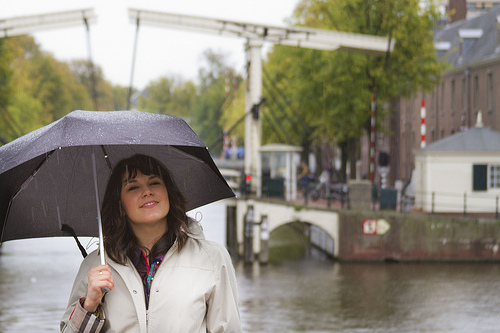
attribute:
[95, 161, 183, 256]
woman — smiling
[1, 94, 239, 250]
umbrella — black, wet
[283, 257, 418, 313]
water — murky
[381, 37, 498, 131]
building — brown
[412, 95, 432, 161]
pole — striples, stripes